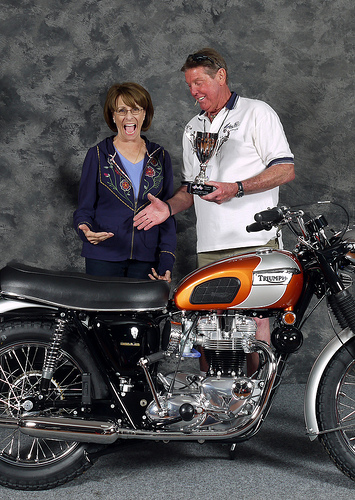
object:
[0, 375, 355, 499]
floor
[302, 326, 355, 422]
fender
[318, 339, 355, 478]
wheel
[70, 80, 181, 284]
lady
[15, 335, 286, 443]
pipe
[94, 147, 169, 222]
embroidery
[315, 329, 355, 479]
tire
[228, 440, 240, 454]
kickstand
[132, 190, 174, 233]
hands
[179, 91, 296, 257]
shirt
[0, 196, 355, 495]
bike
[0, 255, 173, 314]
black seat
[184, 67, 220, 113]
face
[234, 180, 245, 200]
watch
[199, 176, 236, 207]
hand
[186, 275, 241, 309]
black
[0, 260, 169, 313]
seat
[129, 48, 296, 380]
man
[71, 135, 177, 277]
jacket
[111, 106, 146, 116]
glasses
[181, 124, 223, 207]
trophy